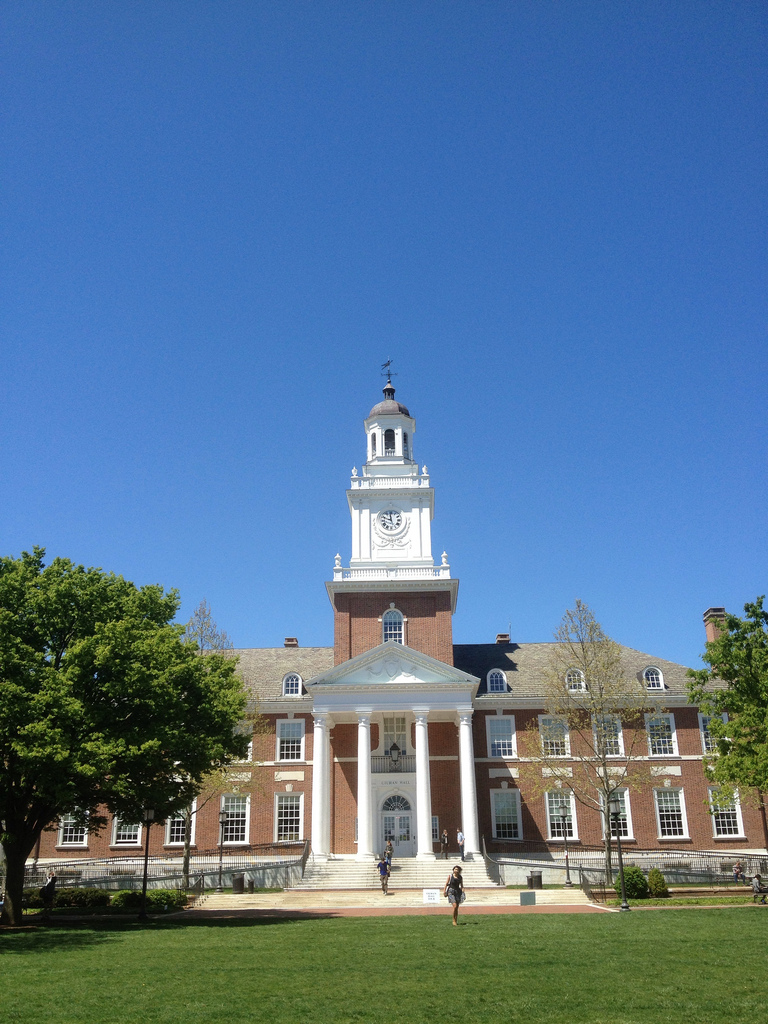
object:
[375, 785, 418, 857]
door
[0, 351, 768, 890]
building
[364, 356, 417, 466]
tower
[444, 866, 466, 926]
person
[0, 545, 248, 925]
trees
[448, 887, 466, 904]
skirt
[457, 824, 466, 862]
person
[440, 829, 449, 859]
person